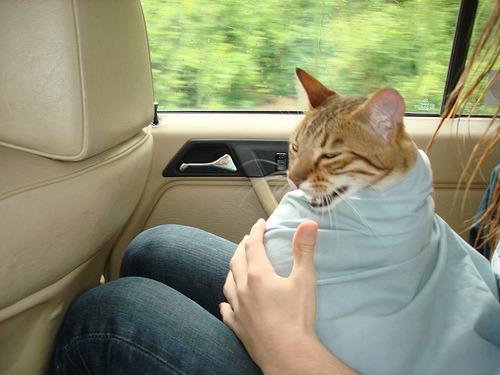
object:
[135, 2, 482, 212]
car door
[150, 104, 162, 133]
lock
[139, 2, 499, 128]
greenery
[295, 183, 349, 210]
mouth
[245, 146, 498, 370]
blanket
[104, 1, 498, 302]
door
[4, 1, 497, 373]
interior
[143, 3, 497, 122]
trees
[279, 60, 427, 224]
head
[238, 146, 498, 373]
sheet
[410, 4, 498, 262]
hair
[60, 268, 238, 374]
lap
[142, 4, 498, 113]
foliage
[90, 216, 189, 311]
knees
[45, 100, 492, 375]
person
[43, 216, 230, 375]
jeans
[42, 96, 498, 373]
girl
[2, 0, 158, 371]
seat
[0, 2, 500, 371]
car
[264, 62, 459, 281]
cat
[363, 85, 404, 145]
ear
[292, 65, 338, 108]
ear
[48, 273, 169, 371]
knee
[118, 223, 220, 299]
knee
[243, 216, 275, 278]
finger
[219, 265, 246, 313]
finger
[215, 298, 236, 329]
finger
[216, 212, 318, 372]
hand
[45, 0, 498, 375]
passenger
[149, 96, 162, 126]
knob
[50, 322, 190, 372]
seam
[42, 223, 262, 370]
dungarees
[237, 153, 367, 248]
whiskers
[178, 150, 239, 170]
handle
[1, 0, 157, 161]
headrest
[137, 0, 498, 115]
window